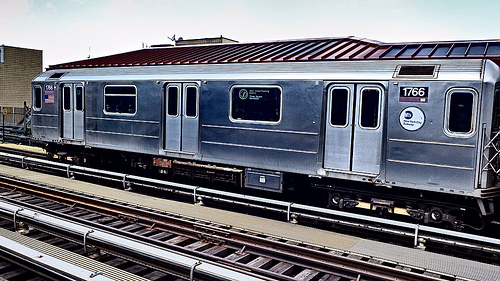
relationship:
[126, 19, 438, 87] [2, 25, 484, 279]
roof of station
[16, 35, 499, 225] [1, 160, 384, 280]
train on a track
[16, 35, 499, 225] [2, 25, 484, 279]
train in station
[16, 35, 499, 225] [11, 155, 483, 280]
train on track